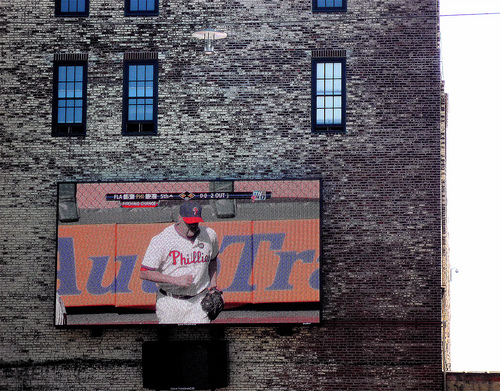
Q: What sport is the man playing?
A: Baseball.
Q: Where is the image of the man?
A: TV.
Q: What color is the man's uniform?
A: White.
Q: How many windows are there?
A: Six.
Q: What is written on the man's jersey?
A: Phillie.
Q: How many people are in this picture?
A: One.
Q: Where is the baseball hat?
A: The man's head.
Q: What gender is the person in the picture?
A: Male.